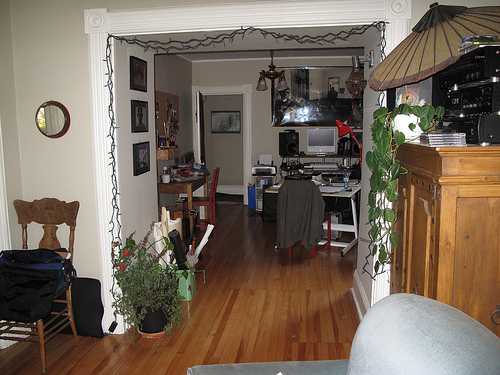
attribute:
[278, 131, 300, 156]
speaker — black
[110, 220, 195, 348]
plant — green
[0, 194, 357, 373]
floor — polished, hardwood, brown, wooden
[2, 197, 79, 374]
chair — old fashioned, wooden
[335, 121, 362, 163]
lamp — red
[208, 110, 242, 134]
picture — hanging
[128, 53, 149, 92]
picture — hanging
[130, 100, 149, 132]
picture — hanging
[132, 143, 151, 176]
picture — hanging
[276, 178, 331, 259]
chair — red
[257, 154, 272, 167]
paper — white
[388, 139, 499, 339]
hutch — brown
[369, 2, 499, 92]
umbrella — tan, brown, paper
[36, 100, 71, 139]
mirror — large, circular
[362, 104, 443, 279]
plant — hanging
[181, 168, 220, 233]
chair — red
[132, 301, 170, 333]
pot — black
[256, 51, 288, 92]
light fixture — ornate, hanging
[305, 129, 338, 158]
monitor — white